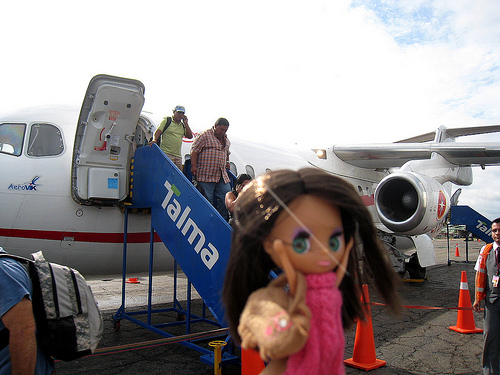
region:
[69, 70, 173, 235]
open door in the side of the airplane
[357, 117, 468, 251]
jet engine on the wing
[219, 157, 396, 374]
doll in a pink sweater dress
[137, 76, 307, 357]
stairs with the Talma logo on the side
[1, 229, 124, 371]
person carrying a backpack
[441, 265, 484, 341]
orange cone with a white stripe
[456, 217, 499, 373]
man wearing an orange vest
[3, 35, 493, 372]
white airplane unloading passengers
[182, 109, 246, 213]
man in a plaid shirt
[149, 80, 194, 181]
man talking on his phone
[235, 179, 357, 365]
doll with pink dress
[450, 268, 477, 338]
orange and white cone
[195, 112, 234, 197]
man with checkered shirt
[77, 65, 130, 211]
door of the airplane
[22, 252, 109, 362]
gray and black backpack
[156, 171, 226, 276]
white word that says talma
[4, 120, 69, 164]
windows of white plane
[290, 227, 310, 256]
eye of the toy doll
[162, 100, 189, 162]
man with green shirt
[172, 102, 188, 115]
white hat on man's head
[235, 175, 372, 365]
Doll wearing pink dress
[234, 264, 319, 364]
Brown cloth doll purse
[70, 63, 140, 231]
Open door of an airplane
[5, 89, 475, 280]
White plane with red stripe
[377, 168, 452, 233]
Engine of plane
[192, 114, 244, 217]
Man in checked shirt walking down stairs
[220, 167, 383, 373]
Doll with brown hair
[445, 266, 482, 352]
Orange traffic cone with white stripe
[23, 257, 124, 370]
Black, white and grey backpack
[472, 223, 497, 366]
Man in airport uniform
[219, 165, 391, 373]
a childs doll with a pink dress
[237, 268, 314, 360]
the childs doll has a tan purse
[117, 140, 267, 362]
a blue airplane ladder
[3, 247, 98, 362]
a black gray and white backpack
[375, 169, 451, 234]
a jet on a small aircraft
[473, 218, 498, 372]
an airport employee in an orange vest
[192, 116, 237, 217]
a man getting off an airplane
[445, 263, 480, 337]
an orange traffic cone on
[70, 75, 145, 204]
an open door on an airplane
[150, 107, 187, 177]
a man exiting an airplane on a cell phone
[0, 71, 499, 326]
passengers departing small jet plane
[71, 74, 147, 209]
open door of plane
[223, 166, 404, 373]
doll with black hair and pink clothes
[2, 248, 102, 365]
grey and black backpack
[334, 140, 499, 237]
jet engine under wing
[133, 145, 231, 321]
stairs leading out of plane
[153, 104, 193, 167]
passenger wearing yellow shirt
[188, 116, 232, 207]
passenger wearing plaid shirt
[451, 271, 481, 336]
orange safety cone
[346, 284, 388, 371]
orange safety cone behind doll's hair